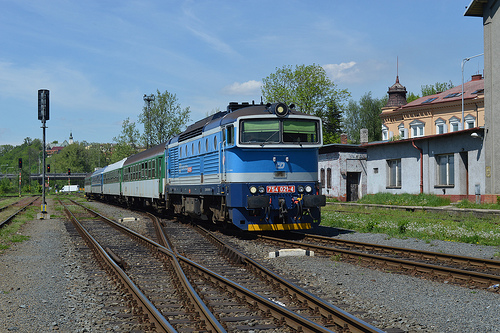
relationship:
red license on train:
[264, 185, 298, 195] [65, 100, 322, 235]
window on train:
[151, 160, 156, 177] [94, 95, 336, 247]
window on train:
[146, 160, 153, 180] [94, 95, 336, 247]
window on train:
[139, 162, 144, 179] [94, 95, 336, 247]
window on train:
[130, 165, 137, 180] [94, 95, 336, 247]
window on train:
[124, 167, 131, 181] [94, 95, 336, 247]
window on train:
[230, 114, 280, 144] [64, 68, 343, 240]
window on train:
[278, 110, 323, 145] [64, 68, 343, 240]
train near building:
[94, 95, 336, 247] [346, 123, 498, 211]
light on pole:
[35, 88, 51, 120] [35, 124, 52, 221]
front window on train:
[239, 116, 321, 147] [65, 100, 322, 235]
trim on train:
[246, 220, 316, 235] [94, 95, 336, 247]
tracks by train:
[118, 204, 325, 307] [86, 109, 358, 248]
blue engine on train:
[166, 95, 326, 230] [94, 95, 336, 247]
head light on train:
[265, 95, 300, 125] [49, 128, 354, 249]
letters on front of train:
[262, 180, 307, 197] [65, 100, 322, 235]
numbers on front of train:
[266, 179, 309, 197] [65, 100, 322, 235]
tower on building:
[384, 58, 407, 104] [380, 56, 482, 129]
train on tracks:
[94, 95, 336, 247] [205, 217, 499, 293]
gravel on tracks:
[111, 213, 398, 331] [178, 222, 498, 331]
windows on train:
[117, 160, 162, 180] [94, 95, 336, 247]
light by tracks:
[34, 84, 52, 221] [57, 192, 499, 332]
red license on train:
[264, 185, 298, 195] [160, 96, 342, 236]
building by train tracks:
[318, 125, 488, 207] [68, 189, 498, 330]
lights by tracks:
[8, 85, 78, 185] [34, 207, 474, 330]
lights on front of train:
[220, 155, 332, 215] [92, 90, 475, 247]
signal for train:
[34, 85, 52, 125] [94, 95, 336, 247]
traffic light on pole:
[36, 87, 53, 121] [35, 118, 52, 204]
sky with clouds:
[2, 1, 482, 142] [228, 74, 265, 98]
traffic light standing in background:
[15, 155, 25, 170] [2, 59, 483, 187]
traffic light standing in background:
[42, 160, 53, 172] [2, 59, 483, 187]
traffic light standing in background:
[65, 167, 74, 181] [2, 59, 483, 187]